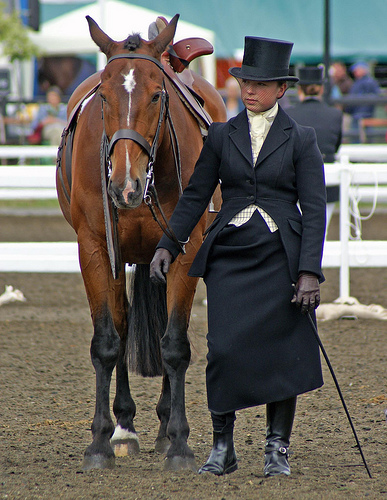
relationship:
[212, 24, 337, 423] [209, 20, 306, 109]
woman wears hat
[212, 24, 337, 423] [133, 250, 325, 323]
woman wears gloves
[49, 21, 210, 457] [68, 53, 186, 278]
horse has reigns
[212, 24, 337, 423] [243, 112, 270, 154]
woman wears shirt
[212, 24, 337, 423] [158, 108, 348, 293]
woman wears coat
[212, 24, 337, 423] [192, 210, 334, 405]
woman wears skirt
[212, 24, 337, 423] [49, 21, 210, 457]
woman with horse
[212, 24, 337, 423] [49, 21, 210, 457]
woman beside horse